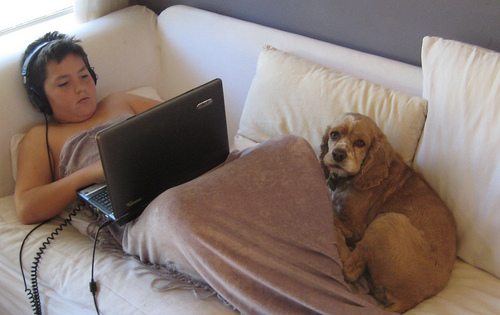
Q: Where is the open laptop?
A: On the boy's lap.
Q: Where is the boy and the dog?
A: On a white sofa.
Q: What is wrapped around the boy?
A: A dusty pink blanket.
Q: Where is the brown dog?
A: At the boy's feet.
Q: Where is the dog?
A: Curled up next to the boy.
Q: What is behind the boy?
A: A window.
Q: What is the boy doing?
A: Writing on the keyboard.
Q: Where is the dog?
A: On the couch.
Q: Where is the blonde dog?
A: On the couch.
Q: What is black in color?
A: Laptop.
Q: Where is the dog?
A: On the person.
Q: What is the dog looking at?
A: The camera.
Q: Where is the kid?
A: On the couch.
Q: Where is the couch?
A: Under the kid.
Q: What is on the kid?
A: Blanket.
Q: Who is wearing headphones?
A: The boy.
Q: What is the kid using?
A: Laptop.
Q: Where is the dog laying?
A: On the boy.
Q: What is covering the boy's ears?
A: Headphones.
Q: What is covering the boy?
A: A blanket.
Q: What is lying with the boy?
A: A dog.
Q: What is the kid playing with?
A: A laptop.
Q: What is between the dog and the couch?
A: Pillows.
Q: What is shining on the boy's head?
A: Sunlight.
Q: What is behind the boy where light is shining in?
A: A window.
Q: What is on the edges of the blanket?
A: Fringes.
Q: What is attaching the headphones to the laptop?
A: A cord.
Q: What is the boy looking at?
A: The laptop.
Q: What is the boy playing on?
A: Computer.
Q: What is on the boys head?
A: Headphones.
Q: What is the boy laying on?
A: Couch.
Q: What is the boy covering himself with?
A: Blanket.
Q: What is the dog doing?
A: Resting.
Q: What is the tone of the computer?
A: Black.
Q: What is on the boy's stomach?
A: Laptop.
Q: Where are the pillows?
A: On the couch.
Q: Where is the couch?
A: Against the wall.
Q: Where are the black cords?
A: Attached to the computer.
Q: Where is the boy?
A: On the couch.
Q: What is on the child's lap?
A: A laptop computer.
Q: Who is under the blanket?
A: The boy on the couch.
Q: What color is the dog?
A: Tan.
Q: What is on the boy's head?
A: Headphones.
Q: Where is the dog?
A: Next to the boy.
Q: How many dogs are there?
A: One.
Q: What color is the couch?
A: White.